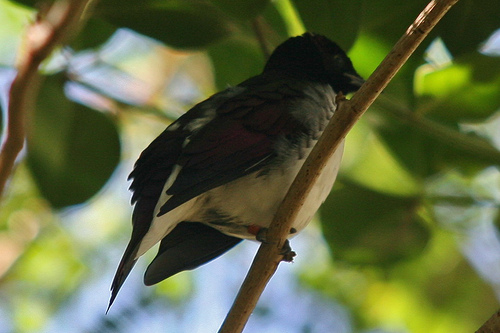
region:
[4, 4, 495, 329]
Bird sitting on a branch among green leaves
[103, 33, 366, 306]
Small black bird with a white breast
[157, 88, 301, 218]
Black bird wing with a tinge of red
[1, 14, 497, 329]
Out of focus green leaves in the background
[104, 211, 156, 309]
Black and white tail feathers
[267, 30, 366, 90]
Bird head covered in black feathers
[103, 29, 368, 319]
Plump bird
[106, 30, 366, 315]
Bird with its toes gripping a bare branch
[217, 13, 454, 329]
Slender brown branch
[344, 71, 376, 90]
Bird's beak partially obscured by a branch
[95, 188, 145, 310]
Bird has black tail feathers.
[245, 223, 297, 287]
Bird has black feet.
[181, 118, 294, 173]
Bird has gray wing.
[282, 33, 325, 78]
Bird has black head.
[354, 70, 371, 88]
Bird has gray beak.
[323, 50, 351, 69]
Bird has dark eye.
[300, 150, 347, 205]
Bird has white chest.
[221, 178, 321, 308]
Bird is standing on branch.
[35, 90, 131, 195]
Green leave on tree branch.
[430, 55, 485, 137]
Green leaf on tree branch.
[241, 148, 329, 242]
bird's belly is white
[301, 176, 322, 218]
bird's belly is white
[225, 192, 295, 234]
bird's belly is white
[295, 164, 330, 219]
bird's belly is white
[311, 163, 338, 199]
bird's belly is white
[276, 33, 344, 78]
bird's head is black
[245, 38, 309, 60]
bird's head is black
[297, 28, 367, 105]
bird's head is black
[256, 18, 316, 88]
bird's head is black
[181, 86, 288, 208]
bird's wing is black and red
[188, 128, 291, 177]
bird's wing is black and red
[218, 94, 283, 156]
bird's wing is black and red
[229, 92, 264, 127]
bird's wing is black and red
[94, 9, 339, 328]
a bird perched on a branch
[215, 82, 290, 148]
Black feathers in the photo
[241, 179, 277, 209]
White feathers in the photo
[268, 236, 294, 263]
Black bird legs in the photo.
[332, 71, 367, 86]
Black beak in the photo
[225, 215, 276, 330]
Twig in the photo.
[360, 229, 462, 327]
Leaves in the photo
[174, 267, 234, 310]
Blue sky in the background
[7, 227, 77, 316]
Yellow leaf in the background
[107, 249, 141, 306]
Black bird's tail in the photo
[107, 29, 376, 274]
Bird perched on a tree